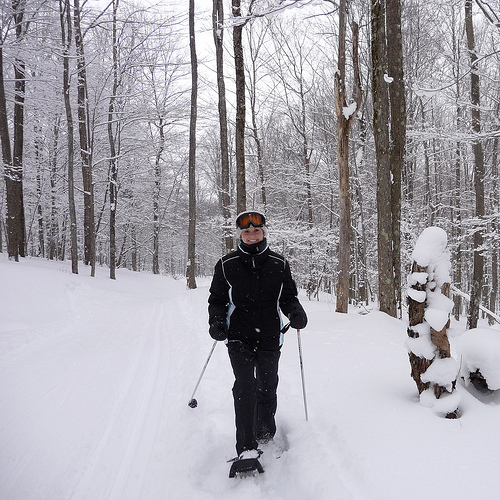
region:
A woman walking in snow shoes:
[183, 210, 306, 497]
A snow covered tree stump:
[404, 227, 466, 424]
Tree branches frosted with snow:
[3, 3, 489, 208]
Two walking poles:
[186, 323, 314, 423]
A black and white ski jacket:
[203, 242, 303, 344]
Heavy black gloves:
[207, 311, 307, 342]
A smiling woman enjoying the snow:
[206, 209, 309, 479]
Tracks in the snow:
[83, 304, 179, 498]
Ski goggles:
[230, 210, 270, 230]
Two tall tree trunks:
[373, 4, 403, 313]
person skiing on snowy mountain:
[193, 200, 303, 464]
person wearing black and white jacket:
[211, 252, 296, 325]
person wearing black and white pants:
[222, 346, 287, 434]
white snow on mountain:
[16, 279, 181, 495]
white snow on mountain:
[321, 325, 398, 482]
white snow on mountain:
[365, 421, 488, 498]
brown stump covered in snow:
[405, 220, 469, 420]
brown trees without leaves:
[6, 12, 128, 264]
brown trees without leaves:
[106, 14, 326, 209]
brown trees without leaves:
[301, 6, 488, 221]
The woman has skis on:
[191, 398, 353, 494]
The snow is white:
[33, 401, 163, 496]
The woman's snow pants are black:
[209, 337, 308, 484]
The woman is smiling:
[231, 213, 291, 258]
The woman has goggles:
[213, 202, 268, 233]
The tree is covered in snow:
[373, 211, 485, 438]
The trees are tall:
[144, 5, 454, 135]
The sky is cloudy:
[236, 23, 377, 127]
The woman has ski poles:
[170, 320, 258, 432]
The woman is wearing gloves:
[286, 307, 319, 333]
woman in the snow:
[187, 206, 311, 478]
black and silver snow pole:
[187, 337, 217, 418]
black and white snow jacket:
[207, 245, 307, 329]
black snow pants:
[225, 334, 282, 451]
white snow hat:
[231, 209, 276, 244]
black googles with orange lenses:
[234, 211, 268, 229]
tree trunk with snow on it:
[402, 217, 463, 428]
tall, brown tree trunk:
[360, 50, 407, 321]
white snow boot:
[235, 451, 264, 463]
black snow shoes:
[224, 457, 268, 481]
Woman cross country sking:
[189, 208, 313, 485]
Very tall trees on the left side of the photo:
[0, 3, 204, 283]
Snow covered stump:
[383, 219, 498, 418]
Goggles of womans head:
[206, 202, 295, 262]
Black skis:
[205, 435, 340, 493]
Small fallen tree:
[433, 280, 496, 340]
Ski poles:
[180, 319, 325, 428]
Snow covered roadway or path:
[124, 292, 360, 495]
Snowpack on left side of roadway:
[0, 258, 167, 499]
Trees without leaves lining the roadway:
[3, 2, 496, 297]